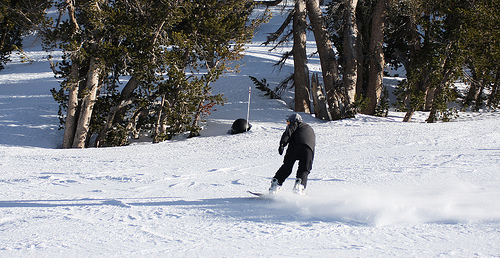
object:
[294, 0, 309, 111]
trees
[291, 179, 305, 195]
boots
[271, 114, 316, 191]
man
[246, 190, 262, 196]
snow board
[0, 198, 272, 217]
shadow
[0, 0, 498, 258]
snow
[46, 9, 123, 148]
evergreen trees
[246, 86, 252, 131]
metal pole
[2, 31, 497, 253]
hill side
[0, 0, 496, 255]
ground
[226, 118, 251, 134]
object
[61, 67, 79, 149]
woods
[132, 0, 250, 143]
trees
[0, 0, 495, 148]
forest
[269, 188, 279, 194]
feet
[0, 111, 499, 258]
slope